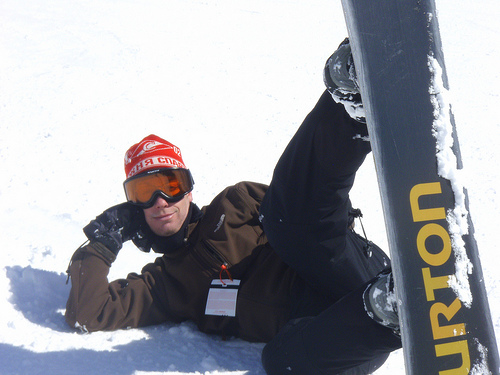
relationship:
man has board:
[62, 36, 402, 375] [352, 5, 499, 373]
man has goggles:
[62, 36, 402, 375] [119, 168, 197, 201]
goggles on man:
[119, 168, 197, 201] [62, 36, 402, 375]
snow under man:
[2, 5, 483, 369] [62, 36, 402, 375]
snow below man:
[2, 5, 483, 369] [62, 36, 402, 375]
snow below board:
[2, 5, 483, 369] [352, 5, 499, 373]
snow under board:
[2, 5, 483, 369] [352, 5, 499, 373]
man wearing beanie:
[66, 36, 402, 373] [119, 134, 187, 172]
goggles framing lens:
[122, 167, 194, 209] [125, 169, 192, 200]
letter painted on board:
[408, 180, 448, 222] [352, 5, 499, 373]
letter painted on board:
[414, 220, 453, 265] [352, 5, 499, 373]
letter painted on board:
[419, 265, 457, 301] [352, 5, 499, 373]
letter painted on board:
[426, 296, 467, 338] [352, 5, 499, 373]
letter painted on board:
[432, 338, 471, 372] [352, 5, 499, 373]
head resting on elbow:
[120, 132, 195, 239] [63, 296, 107, 333]